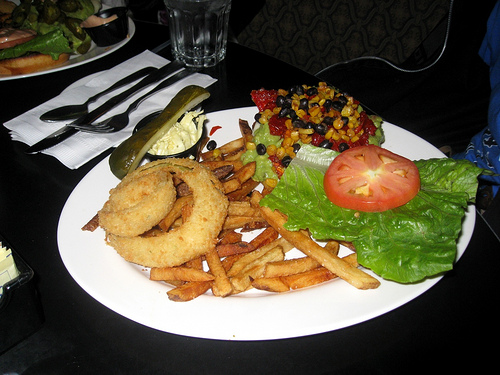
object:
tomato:
[321, 143, 421, 212]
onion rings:
[95, 155, 231, 269]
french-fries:
[244, 188, 381, 292]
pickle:
[107, 85, 212, 182]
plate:
[53, 104, 483, 342]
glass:
[159, 1, 231, 69]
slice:
[322, 142, 422, 212]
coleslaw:
[150, 110, 212, 159]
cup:
[129, 112, 204, 160]